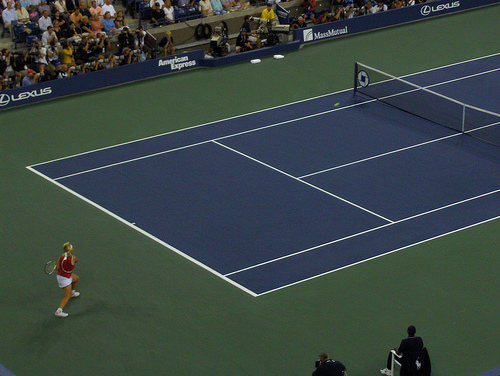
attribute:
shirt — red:
[54, 251, 78, 275]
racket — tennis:
[43, 258, 59, 277]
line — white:
[212, 134, 395, 232]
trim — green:
[4, 1, 484, 373]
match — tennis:
[11, 75, 461, 328]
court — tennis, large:
[13, 10, 479, 373]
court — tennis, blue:
[23, 51, 484, 298]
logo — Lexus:
[416, 0, 468, 13]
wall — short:
[298, 6, 483, 38]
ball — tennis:
[334, 103, 345, 110]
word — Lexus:
[1, 88, 62, 104]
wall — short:
[1, 56, 147, 119]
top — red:
[53, 251, 77, 281]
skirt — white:
[54, 272, 76, 291]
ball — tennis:
[331, 99, 341, 109]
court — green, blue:
[12, 45, 462, 348]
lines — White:
[225, 264, 287, 313]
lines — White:
[218, 254, 302, 324]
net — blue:
[348, 60, 492, 155]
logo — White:
[356, 71, 373, 86]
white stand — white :
[386, 352, 427, 372]